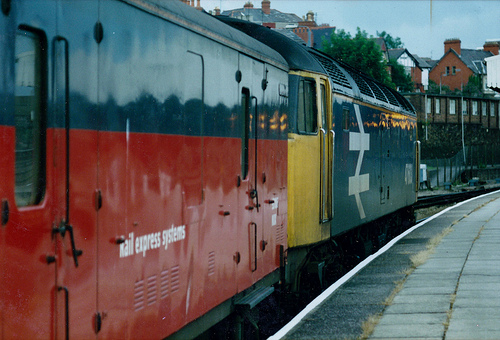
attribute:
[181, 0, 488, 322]
train — yellow, gray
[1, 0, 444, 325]
train — black, yellow, red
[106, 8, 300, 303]
carrier — red, blue, coated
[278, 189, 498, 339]
pavement blocks — stone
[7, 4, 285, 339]
train car — red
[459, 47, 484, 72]
house roof — gray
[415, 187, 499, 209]
track — metal, train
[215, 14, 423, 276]
car — train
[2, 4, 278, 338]
car — train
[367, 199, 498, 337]
stones — grey, paving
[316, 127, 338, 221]
handle — silver